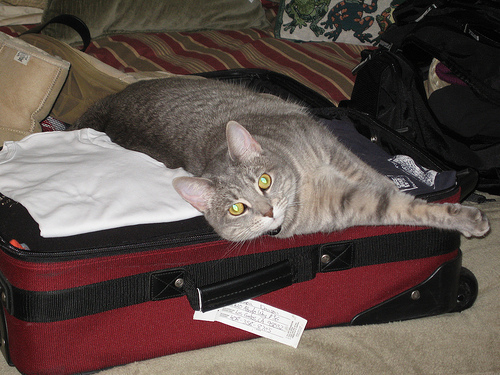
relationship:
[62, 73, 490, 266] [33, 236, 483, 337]
adult cat on suitcase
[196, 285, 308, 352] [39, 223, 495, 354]
bag has a tag on suitcase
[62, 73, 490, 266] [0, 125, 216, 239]
adult cat on clothes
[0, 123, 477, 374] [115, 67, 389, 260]
bag under cat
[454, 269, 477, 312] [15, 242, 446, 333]
black wheel on suitcase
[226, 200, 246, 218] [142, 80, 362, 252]
cat with green eyes on cat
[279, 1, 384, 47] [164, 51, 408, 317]
frog print pillow behind cat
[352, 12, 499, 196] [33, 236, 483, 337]
black bag by suitcase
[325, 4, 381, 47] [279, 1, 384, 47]
frog on frog print pillow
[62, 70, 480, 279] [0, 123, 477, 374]
adult cat laying on bag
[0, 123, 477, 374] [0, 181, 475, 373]
bag on suitcase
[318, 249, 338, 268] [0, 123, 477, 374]
small screw on bag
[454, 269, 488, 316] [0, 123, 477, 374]
black wheel on bag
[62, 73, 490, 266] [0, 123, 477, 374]
adult cat laying on bag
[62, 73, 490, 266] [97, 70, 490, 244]
adult cat has fur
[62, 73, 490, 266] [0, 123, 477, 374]
adult cat on bag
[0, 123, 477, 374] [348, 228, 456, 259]
bag has black trim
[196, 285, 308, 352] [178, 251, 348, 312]
bag has a tag on handle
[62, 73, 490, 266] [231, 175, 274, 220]
adult cat has eyes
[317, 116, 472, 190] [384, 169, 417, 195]
clothing has white design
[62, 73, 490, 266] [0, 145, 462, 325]
adult cat on bag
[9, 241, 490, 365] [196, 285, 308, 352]
bag has bag has a tag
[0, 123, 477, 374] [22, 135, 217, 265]
bag has clothes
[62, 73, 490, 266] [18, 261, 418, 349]
adult cat took over suitcase